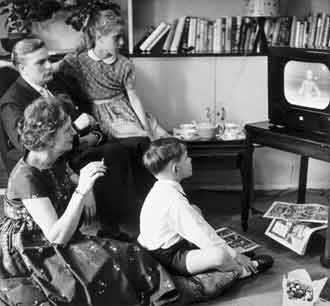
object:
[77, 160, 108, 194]
hand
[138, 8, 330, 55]
books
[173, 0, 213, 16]
wall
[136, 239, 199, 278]
shorts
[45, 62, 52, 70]
nose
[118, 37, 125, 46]
nose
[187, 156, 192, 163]
nose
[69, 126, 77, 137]
nose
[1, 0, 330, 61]
book shelf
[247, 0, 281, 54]
small lamp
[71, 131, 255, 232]
table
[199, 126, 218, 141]
pitcher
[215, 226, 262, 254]
newspaper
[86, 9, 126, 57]
head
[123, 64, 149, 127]
arm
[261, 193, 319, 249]
newspaper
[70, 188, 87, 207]
wrist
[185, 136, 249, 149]
tray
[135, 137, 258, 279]
boy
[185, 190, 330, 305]
carpet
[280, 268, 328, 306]
container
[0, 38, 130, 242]
man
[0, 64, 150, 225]
chair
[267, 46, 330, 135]
television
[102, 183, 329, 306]
floor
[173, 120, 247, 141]
cups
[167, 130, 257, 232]
coffee table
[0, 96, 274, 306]
woman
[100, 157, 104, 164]
cigarette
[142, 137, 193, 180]
head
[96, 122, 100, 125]
cigratte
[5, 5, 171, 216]
girl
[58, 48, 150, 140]
dress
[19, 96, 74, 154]
hair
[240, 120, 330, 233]
shelf